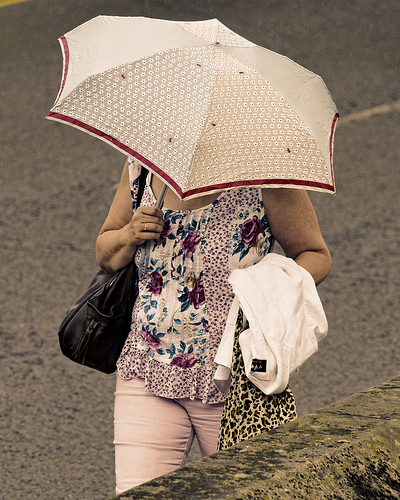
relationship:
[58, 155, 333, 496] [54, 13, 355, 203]
lady holding umbrella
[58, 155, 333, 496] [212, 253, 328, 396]
lady carrying clothing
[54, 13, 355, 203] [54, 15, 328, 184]
umbrella with design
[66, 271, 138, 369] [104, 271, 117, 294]
purse with zippers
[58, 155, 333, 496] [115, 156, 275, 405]
lady wearing blouse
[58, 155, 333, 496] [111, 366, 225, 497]
lady wearing pants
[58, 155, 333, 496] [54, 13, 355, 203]
lady under umbrella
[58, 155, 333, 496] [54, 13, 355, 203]
lady with umbrella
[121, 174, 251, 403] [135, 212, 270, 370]
blouse with flowers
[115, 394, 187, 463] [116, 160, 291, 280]
pants on woman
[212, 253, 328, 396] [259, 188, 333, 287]
clothing over arm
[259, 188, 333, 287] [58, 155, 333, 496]
arm of lady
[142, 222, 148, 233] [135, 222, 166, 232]
ring on finger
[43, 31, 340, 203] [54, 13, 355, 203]
line bordering umbrella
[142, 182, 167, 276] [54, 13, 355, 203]
pole on umbrella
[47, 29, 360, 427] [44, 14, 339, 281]
lady carrying umbrella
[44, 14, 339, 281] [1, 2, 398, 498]
umbrella in rain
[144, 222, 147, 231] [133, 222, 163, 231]
ring on finger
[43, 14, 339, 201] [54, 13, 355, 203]
design on umbrella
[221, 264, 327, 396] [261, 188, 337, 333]
clothing draped over arm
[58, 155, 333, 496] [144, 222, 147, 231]
lady wearing ring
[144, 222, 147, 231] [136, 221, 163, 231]
ring on finger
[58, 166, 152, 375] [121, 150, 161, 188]
purse draped over shoulder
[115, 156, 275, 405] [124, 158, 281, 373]
blouse on blouse